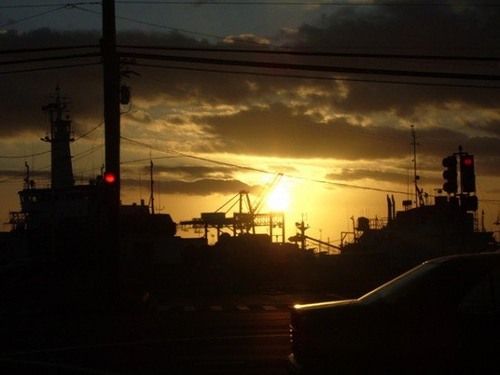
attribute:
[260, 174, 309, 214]
sun — bright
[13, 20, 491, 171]
sky — cloudy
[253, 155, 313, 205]
sun — shining, brightly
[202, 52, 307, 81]
clouds — grey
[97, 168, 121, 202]
light — red, on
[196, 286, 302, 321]
lines — black, white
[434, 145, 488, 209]
light — signal, on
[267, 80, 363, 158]
sky — grey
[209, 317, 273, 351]
road — grey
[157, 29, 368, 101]
lines — wire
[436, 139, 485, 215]
light — red, street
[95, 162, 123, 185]
light — red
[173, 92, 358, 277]
sun — bright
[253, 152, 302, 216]
sun — bright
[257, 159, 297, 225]
sun — bright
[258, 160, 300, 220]
sun — bright